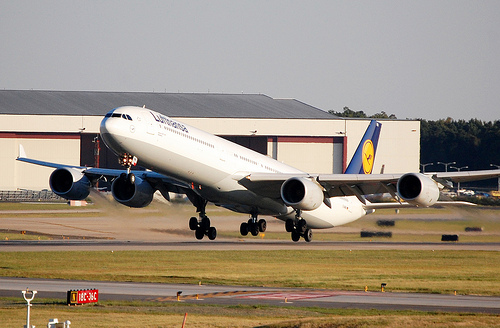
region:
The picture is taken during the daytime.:
[2, 5, 496, 325]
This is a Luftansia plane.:
[87, 86, 419, 250]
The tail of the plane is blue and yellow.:
[328, 103, 393, 197]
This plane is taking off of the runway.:
[8, 73, 490, 299]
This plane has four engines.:
[44, 143, 499, 306]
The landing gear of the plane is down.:
[166, 192, 333, 248]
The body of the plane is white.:
[114, 103, 362, 227]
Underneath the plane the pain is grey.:
[125, 145, 317, 265]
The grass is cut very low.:
[172, 245, 497, 300]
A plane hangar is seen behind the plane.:
[262, 93, 456, 208]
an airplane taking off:
[10, 103, 496, 250]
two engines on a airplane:
[274, 169, 448, 212]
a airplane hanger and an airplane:
[8, 107, 427, 237]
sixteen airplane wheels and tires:
[185, 209, 320, 244]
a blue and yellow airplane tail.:
[344, 116, 382, 171]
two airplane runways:
[11, 233, 498, 311]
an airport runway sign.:
[61, 284, 109, 309]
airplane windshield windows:
[92, 107, 139, 127]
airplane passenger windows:
[142, 124, 224, 154]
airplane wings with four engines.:
[12, 156, 496, 210]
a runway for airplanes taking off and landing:
[0, 245, 495, 315]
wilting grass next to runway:
[5, 240, 495, 290]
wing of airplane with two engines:
[255, 165, 495, 205]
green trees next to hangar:
[420, 120, 495, 165]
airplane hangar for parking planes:
[0, 85, 420, 200]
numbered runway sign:
[55, 280, 110, 300]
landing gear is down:
[185, 210, 320, 245]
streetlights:
[420, 155, 470, 185]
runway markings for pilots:
[167, 290, 367, 305]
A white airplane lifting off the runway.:
[13, 100, 494, 245]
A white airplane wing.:
[251, 156, 496, 183]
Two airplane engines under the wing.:
[280, 175, 437, 205]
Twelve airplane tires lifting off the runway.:
[180, 215, 320, 245]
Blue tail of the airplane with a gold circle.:
[337, 111, 379, 171]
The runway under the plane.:
[3, 235, 493, 256]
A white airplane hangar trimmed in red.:
[5, 85, 420, 187]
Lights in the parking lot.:
[420, 156, 495, 172]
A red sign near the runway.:
[65, 285, 105, 310]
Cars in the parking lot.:
[442, 182, 497, 207]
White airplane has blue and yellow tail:
[15, 100, 498, 256]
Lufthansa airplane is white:
[15, 95, 497, 241]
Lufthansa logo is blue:
[140, 103, 196, 138]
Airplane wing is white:
[240, 162, 496, 193]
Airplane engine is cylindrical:
[280, 176, 331, 212]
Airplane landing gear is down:
[165, 190, 325, 258]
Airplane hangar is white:
[0, 80, 422, 206]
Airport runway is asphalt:
[0, 265, 496, 320]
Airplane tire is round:
[235, 220, 250, 235]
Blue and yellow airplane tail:
[341, 115, 386, 179]